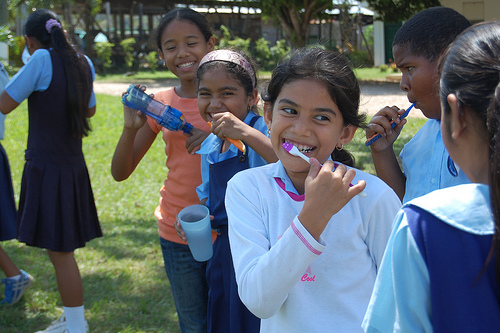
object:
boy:
[385, 7, 472, 200]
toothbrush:
[363, 100, 416, 144]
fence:
[72, 2, 375, 66]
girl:
[121, 14, 213, 312]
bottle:
[123, 88, 195, 138]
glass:
[177, 203, 212, 268]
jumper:
[12, 44, 107, 251]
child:
[218, 30, 418, 333]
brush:
[275, 136, 303, 159]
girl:
[166, 60, 293, 329]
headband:
[189, 42, 274, 80]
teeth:
[310, 148, 312, 150]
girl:
[376, 28, 496, 329]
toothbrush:
[205, 118, 246, 152]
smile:
[173, 59, 199, 71]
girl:
[248, 55, 393, 326]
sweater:
[225, 163, 402, 327]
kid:
[236, 55, 388, 325]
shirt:
[142, 87, 211, 242]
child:
[111, 6, 216, 329]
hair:
[20, 5, 95, 142]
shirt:
[223, 159, 400, 329]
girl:
[3, 11, 94, 327]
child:
[360, 16, 497, 330]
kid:
[0, 3, 98, 331]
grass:
[95, 264, 173, 326]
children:
[111, 0, 497, 332]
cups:
[109, 76, 225, 265]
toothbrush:
[277, 135, 341, 183]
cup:
[180, 204, 214, 263]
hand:
[175, 211, 214, 242]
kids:
[111, 11, 207, 331]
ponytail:
[45, 17, 94, 141]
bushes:
[0, 0, 380, 62]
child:
[0, 7, 105, 331]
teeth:
[297, 144, 303, 151]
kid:
[181, 48, 281, 331]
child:
[172, 46, 279, 331]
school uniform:
[3, 49, 101, 254]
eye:
[312, 111, 333, 124]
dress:
[12, 49, 106, 254]